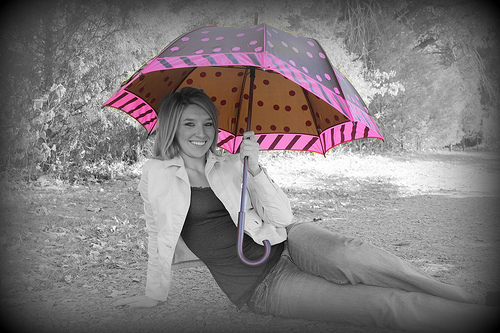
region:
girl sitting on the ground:
[77, 24, 499, 317]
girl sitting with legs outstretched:
[90, 92, 485, 328]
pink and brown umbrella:
[87, 19, 375, 204]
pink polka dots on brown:
[187, 21, 329, 72]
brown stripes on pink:
[142, 48, 316, 76]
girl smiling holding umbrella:
[119, 74, 381, 331]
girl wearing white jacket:
[93, 85, 338, 331]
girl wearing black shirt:
[103, 83, 312, 328]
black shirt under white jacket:
[93, 113, 335, 317]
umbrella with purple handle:
[129, 25, 368, 332]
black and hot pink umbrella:
[98, 16, 388, 272]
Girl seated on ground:
[136, 81, 490, 331]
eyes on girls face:
[182, 116, 214, 130]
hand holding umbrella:
[237, 124, 262, 179]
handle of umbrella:
[236, 195, 273, 265]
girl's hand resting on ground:
[110, 283, 169, 312]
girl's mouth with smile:
[187, 137, 210, 147]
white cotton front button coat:
[127, 150, 296, 306]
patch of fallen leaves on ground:
[13, 182, 120, 287]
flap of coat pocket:
[244, 211, 262, 234]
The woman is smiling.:
[142, 82, 229, 171]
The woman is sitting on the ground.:
[76, 4, 498, 331]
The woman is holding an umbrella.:
[88, 5, 391, 285]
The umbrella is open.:
[98, 9, 387, 291]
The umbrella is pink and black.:
[102, 8, 388, 283]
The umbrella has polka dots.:
[99, 7, 390, 280]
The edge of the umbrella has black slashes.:
[86, 5, 391, 285]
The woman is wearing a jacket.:
[94, 6, 401, 331]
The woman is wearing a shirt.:
[98, 8, 387, 320]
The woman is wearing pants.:
[96, 9, 498, 330]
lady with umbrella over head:
[75, 26, 407, 313]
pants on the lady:
[273, 223, 388, 324]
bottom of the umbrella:
[208, 206, 275, 301]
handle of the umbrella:
[218, 98, 272, 191]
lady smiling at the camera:
[158, 91, 238, 164]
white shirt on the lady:
[128, 178, 192, 271]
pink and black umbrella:
[251, 20, 365, 124]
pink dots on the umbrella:
[276, 42, 316, 68]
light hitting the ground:
[365, 146, 445, 201]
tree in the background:
[20, 46, 116, 107]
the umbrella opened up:
[101, 24, 383, 265]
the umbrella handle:
[236, 210, 271, 265]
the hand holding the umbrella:
[239, 131, 259, 174]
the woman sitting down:
[111, 85, 498, 329]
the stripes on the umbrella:
[98, 49, 385, 159]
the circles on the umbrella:
[122, 22, 372, 134]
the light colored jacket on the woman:
[138, 148, 293, 300]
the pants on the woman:
[245, 216, 498, 331]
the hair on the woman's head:
[151, 85, 221, 161]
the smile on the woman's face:
[188, 138, 206, 147]